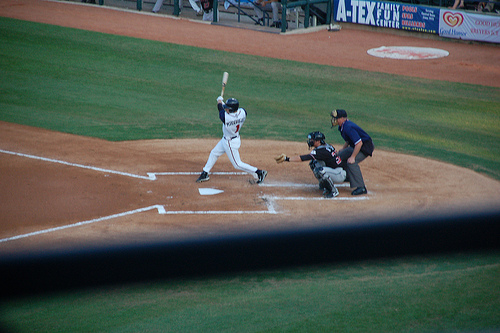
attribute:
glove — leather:
[272, 150, 289, 165]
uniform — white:
[202, 112, 258, 174]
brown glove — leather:
[272, 151, 289, 165]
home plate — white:
[196, 185, 225, 193]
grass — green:
[1, 14, 496, 331]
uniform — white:
[195, 97, 272, 179]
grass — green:
[401, 87, 458, 124]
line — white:
[0, 147, 157, 177]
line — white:
[3, 195, 159, 246]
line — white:
[145, 167, 252, 180]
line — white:
[155, 202, 275, 216]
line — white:
[257, 191, 365, 202]